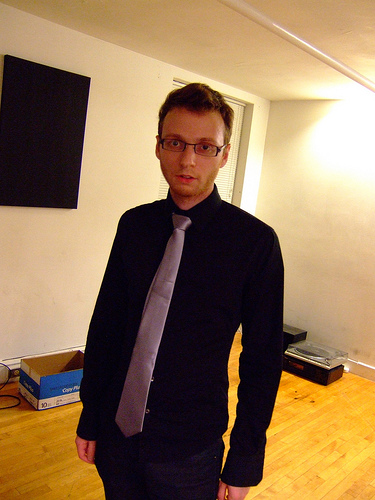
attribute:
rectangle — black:
[6, 53, 86, 220]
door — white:
[231, 100, 262, 204]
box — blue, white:
[17, 349, 84, 410]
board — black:
[8, 62, 93, 199]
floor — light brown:
[278, 376, 369, 493]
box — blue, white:
[15, 345, 84, 413]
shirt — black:
[72, 182, 277, 480]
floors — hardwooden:
[15, 326, 365, 497]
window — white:
[169, 80, 247, 208]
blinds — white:
[174, 83, 244, 206]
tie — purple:
[113, 209, 192, 440]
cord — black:
[2, 391, 24, 411]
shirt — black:
[71, 183, 285, 459]